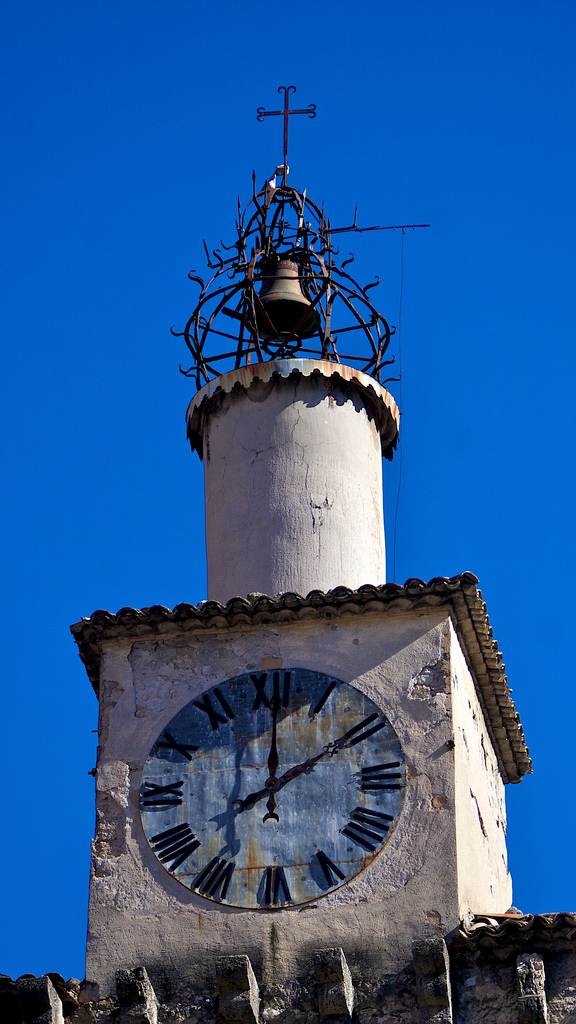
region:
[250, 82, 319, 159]
A metal cross on top of a bell tower.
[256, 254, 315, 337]
A metal bell on top of a clock tower.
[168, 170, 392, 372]
A metal enclosure surrounding a bell.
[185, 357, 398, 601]
A metal and stone column holding a bell and cross.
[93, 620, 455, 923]
An old, stone clock tower.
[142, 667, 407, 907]
A large clock with roman numerals.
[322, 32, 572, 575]
A clear, blue sky.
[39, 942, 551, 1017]
Stone supports for a clock tower.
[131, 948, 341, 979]
this are rocks of an old building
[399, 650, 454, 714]
Cracks and missing stone on a clock tower.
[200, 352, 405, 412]
Rusted metal on top of a clock tower.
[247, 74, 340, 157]
A cross on the top of the tower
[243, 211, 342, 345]
A bell on top of a tower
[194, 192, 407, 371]
Some kind of iron work design.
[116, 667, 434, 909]
A clock on a tower.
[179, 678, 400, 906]
Roman numerals on a clock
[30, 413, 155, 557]
Blue sky above the tower.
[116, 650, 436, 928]
The clock says 2:00.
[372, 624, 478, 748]
A chunk of material is missing.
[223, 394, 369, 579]
There are cracks in the material.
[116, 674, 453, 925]
It looks like rust on the clock.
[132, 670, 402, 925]
Clock face on a tower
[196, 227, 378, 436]
Bell in a tower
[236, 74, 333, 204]
Iron cross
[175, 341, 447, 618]
Cylindrical top of building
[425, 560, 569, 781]
Tile roofing on tower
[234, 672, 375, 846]
Hour and minute hands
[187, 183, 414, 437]
Iron cage protecting metal bell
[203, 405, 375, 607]
Stucco facade building style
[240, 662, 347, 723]
Roman numerals on a clock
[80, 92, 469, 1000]
Clock tower on blue sky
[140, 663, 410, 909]
A clock face with Roman numerals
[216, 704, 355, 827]
Hands on a clock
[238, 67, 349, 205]
An cross with curves at the ends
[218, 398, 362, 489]
Cracks in the building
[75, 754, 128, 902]
Hole in the plaster of a building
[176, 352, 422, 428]
Rusty metal roof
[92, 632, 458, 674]
Eroding plaster on a building.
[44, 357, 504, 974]
Old clock tower.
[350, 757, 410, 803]
The roman numeral three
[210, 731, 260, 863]
Shadow of clock hands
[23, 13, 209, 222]
deep azure blue sky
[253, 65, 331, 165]
Greek cross atop a clock tower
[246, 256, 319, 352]
metal bell atop a clock tower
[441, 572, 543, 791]
clock tower roof tiles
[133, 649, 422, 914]
clock face reading 2 o'clock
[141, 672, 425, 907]
clock face with hours defined in Roman numerals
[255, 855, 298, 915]
upside down Roman numeral 6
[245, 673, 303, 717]
right side up Roman numeral 12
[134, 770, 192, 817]
Roman numeral 9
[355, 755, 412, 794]
Roman numeral 3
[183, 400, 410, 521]
tower has cracks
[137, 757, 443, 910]
watch has no cover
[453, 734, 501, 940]
building is old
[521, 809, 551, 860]
sky is blue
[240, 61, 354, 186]
metals are on top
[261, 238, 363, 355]
an old bell is ontop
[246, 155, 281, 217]
metals has sharp edge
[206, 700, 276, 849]
a shadow on the clock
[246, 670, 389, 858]
clock is saying 12.10